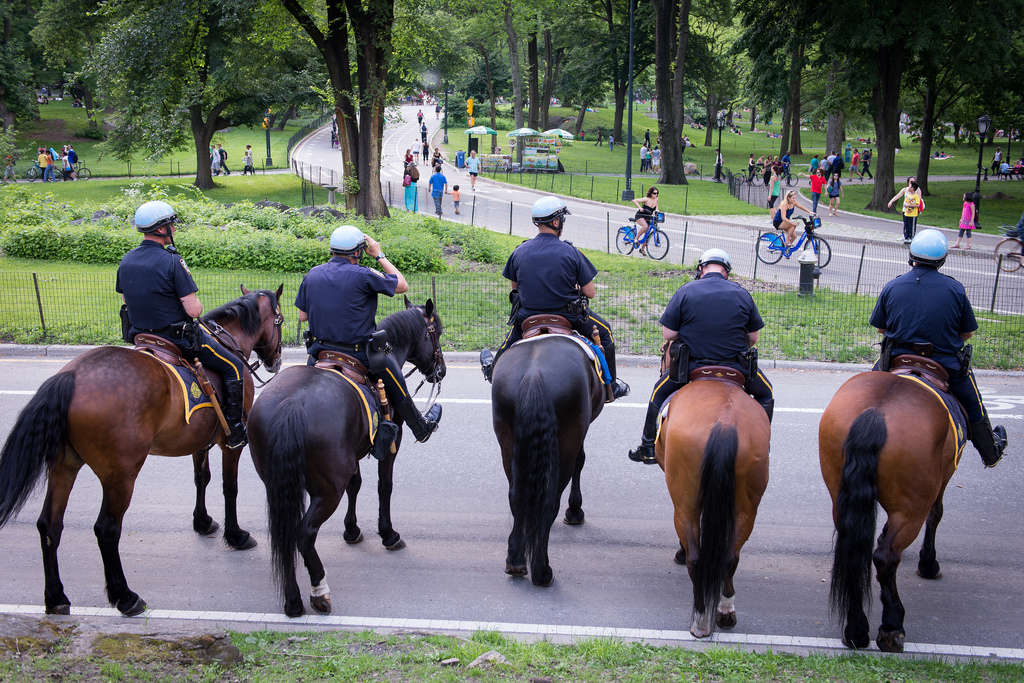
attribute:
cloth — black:
[142, 336, 250, 417]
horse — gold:
[0, 276, 286, 625]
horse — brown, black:
[252, 292, 450, 616]